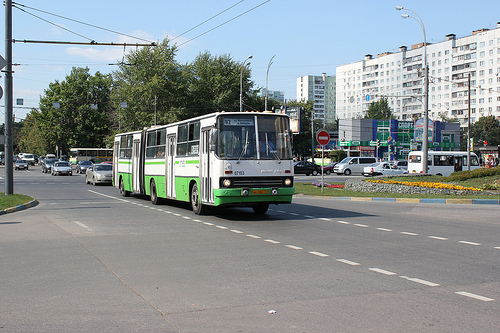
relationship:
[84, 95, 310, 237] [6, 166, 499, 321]
bus on road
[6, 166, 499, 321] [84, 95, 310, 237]
road under bus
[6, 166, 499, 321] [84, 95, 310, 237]
road below bus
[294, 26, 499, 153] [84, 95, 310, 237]
building beside bus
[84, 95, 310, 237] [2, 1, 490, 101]
bus under sky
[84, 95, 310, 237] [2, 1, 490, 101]
bus below sky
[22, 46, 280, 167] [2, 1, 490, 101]
trees below sky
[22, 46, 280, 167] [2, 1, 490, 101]
trees under sky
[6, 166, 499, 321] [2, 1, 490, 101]
road under sky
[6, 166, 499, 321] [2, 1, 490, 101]
road below sky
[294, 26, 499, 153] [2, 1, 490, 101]
building under sky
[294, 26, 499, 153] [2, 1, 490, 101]
building below sky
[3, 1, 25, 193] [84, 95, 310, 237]
post beside bus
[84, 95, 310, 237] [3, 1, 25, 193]
bus beside post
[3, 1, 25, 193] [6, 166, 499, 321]
post on road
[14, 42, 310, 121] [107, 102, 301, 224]
trees behind bus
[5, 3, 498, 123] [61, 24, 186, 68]
sky has clouds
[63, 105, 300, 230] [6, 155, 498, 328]
buses driving on street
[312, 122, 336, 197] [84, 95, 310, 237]
sign next to bus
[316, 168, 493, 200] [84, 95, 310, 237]
flowers next to bus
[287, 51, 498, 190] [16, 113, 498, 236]
buildings behind cars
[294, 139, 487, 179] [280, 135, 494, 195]
cars in lot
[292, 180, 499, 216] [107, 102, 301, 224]
curb next to bus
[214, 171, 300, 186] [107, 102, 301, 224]
headlights on front of bus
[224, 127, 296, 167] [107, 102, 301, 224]
wipers on bus